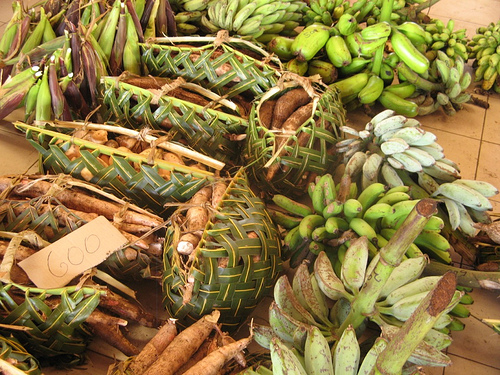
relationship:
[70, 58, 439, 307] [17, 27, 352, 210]
food stored in baskets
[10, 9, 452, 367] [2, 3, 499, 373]
fruit on ground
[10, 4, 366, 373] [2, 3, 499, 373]
root vegetables on ground